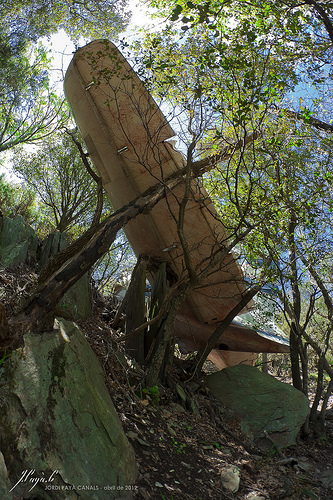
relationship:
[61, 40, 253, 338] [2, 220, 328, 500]
rock on hillside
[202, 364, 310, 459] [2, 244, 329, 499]
leaves are lying in dirt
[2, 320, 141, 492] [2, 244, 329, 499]
leaves are lying in dirt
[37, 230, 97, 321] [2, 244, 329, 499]
leaves are lying in dirt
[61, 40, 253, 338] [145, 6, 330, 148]
rock in tree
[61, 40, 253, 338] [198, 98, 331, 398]
rock in tree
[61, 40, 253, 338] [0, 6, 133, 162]
rock in tree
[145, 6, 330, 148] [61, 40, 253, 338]
tree holding up a rock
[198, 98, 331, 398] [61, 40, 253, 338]
tree holding up a rock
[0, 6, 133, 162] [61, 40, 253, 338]
tree holding up a rock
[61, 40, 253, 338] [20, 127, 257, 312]
rock over trunk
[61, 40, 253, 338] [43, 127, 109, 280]
rock over trunk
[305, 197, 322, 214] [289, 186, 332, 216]
leaf covered brances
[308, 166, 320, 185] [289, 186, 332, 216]
leaf covered brances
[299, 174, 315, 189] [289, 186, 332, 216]
leaf covered brances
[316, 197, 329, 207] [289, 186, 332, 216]
leaf covered brances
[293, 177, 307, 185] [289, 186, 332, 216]
leaf covered brances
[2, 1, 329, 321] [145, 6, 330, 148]
sky visible through tree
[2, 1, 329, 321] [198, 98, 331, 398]
sky visible through tree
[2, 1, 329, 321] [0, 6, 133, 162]
sky visible through tree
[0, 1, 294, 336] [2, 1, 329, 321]
cloud in sky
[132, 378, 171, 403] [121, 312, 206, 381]
mass growing against base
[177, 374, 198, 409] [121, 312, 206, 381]
mass growing against base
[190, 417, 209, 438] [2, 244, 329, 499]
leaf in dirt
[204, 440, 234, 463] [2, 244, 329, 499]
leaf in dirt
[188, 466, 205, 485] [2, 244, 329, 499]
leaf in dirt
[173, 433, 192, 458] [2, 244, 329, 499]
leaf in dirt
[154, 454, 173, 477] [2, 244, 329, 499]
leaf in dirt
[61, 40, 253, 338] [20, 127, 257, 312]
rock hanging between trunk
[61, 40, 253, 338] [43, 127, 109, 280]
rock hanging between trunk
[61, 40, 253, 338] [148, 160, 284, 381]
rock hanging between trunk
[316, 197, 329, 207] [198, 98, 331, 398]
leaf in tree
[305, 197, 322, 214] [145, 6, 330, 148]
leaf in tree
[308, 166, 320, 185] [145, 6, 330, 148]
leaf in tree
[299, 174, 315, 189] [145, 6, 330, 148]
leaf in tree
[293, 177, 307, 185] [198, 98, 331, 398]
leaf in tree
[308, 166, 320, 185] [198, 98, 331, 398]
leaf in tree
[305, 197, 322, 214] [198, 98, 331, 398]
leaf in tree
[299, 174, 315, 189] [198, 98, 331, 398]
leaf in tree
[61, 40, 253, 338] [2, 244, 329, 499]
rock in dirt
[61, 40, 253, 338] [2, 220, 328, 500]
rock in hillside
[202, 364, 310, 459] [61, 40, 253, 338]
leaves are under rock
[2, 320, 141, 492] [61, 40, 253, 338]
leaves are under rock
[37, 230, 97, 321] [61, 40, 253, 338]
leaves are under rock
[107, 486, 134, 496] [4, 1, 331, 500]
2012 in picture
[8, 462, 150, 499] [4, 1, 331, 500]
watermark in picture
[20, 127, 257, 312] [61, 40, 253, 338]
trunk under rock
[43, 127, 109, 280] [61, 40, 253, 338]
trunk under rock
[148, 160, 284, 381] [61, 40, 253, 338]
trunk under rock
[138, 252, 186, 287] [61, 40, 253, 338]
weeds are under rock